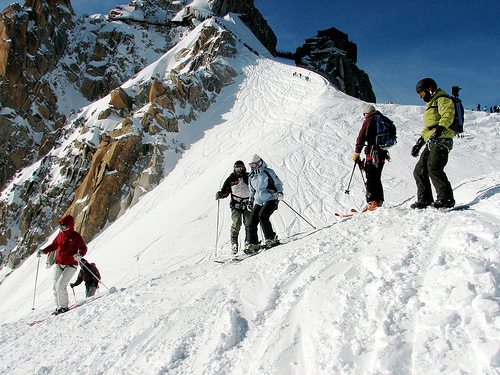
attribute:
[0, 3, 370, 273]
rocks — snow covered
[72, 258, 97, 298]
skier — in distance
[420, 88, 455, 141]
parka — ryellow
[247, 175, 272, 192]
jacket — blue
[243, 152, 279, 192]
skier — female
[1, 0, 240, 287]
rocky mountainside — snowy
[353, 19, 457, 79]
sky — bright blue, in background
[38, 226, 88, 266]
jacket — red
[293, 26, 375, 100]
rocky — outcrop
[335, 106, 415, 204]
man — white, ski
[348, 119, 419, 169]
outfit — black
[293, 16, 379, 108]
rock — big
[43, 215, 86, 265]
jacket — red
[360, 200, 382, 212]
ski boots — red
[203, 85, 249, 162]
track — ski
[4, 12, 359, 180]
mountain — rocky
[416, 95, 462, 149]
jacket — yellow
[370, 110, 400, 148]
backpack — blue